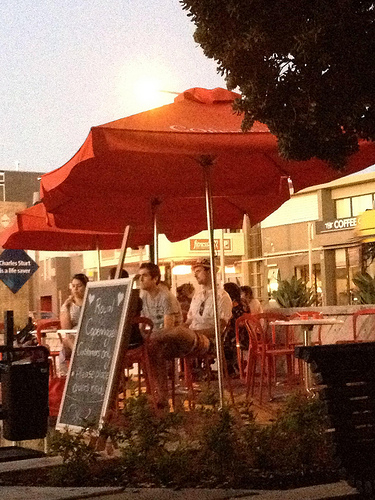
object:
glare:
[117, 54, 173, 115]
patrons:
[58, 255, 264, 411]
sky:
[0, 0, 246, 173]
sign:
[0, 249, 40, 293]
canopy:
[39, 87, 375, 243]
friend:
[59, 273, 90, 370]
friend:
[139, 262, 183, 395]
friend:
[148, 256, 233, 417]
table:
[269, 319, 344, 399]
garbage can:
[0, 345, 52, 442]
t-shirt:
[141, 284, 184, 331]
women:
[223, 282, 252, 379]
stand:
[200, 155, 225, 410]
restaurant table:
[56, 327, 150, 414]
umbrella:
[0, 202, 153, 252]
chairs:
[235, 307, 375, 404]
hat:
[191, 257, 219, 273]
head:
[191, 259, 217, 285]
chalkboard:
[54, 277, 139, 439]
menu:
[54, 277, 134, 437]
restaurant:
[0, 87, 375, 500]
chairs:
[183, 314, 236, 410]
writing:
[0, 259, 31, 274]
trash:
[12, 357, 32, 366]